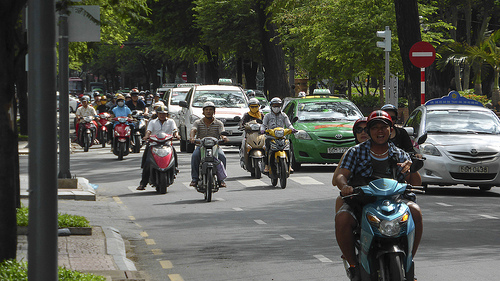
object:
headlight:
[377, 219, 401, 237]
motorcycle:
[339, 177, 426, 281]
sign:
[408, 40, 437, 68]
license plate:
[326, 147, 350, 153]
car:
[280, 88, 370, 171]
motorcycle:
[260, 125, 298, 189]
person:
[260, 97, 297, 175]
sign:
[423, 90, 485, 107]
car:
[403, 88, 499, 190]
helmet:
[269, 97, 283, 110]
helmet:
[202, 100, 215, 109]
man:
[188, 100, 229, 187]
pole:
[385, 51, 391, 105]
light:
[375, 26, 391, 52]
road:
[0, 112, 500, 281]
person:
[334, 108, 424, 281]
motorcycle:
[188, 135, 229, 202]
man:
[135, 105, 183, 190]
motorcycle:
[141, 131, 179, 195]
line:
[127, 215, 137, 222]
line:
[252, 218, 267, 225]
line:
[436, 202, 455, 207]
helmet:
[366, 109, 394, 126]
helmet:
[156, 105, 169, 114]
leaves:
[300, 28, 304, 32]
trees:
[67, 34, 109, 92]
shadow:
[225, 184, 283, 193]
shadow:
[151, 198, 218, 207]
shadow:
[105, 190, 170, 198]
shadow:
[223, 175, 257, 181]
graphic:
[313, 123, 354, 130]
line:
[411, 51, 434, 57]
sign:
[313, 88, 332, 94]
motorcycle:
[237, 118, 269, 179]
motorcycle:
[104, 115, 136, 161]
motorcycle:
[70, 115, 100, 152]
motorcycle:
[93, 111, 114, 148]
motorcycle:
[128, 109, 149, 153]